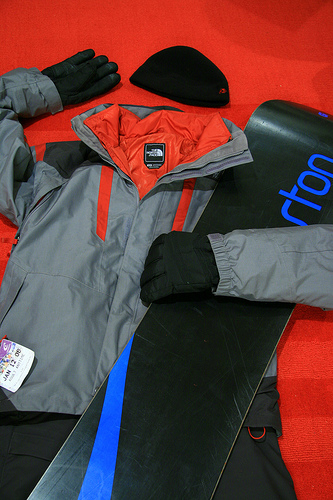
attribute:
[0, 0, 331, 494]
surface — bright, orange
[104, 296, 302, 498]
skipants — black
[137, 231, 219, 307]
glove — black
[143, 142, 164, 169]
tag — black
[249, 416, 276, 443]
tag — orange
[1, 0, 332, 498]
material — red, two tone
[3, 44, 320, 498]
coat — Red, gray, black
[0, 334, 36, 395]
ticket — white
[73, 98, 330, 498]
snowboard — black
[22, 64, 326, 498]
snowboard — black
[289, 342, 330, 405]
blanket — red, striped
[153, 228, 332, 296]
coat sleeve — empty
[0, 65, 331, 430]
grey jacket — gray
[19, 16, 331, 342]
background — orange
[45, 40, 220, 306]
gloves — black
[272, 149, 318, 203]
logo — blue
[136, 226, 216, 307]
glove — black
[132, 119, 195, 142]
jacket — orange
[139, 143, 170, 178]
logo — silver, black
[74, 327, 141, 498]
strip — blue 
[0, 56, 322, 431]
jacket — cloth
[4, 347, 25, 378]
writing — black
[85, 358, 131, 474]
design — blue